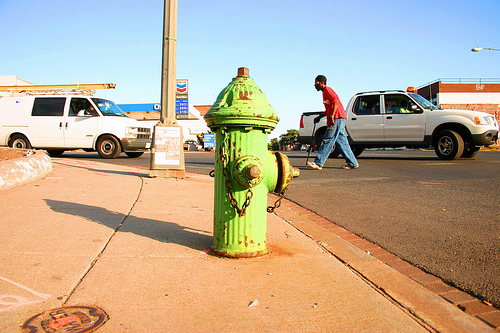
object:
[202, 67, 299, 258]
hydrant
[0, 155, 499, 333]
sidewalk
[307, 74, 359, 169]
person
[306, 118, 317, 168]
cane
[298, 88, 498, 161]
vehicle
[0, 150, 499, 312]
street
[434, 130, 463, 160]
wheel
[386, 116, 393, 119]
handles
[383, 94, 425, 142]
door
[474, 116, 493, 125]
headlight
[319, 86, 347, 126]
shirt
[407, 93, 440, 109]
windshield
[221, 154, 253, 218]
chain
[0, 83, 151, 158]
van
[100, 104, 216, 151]
station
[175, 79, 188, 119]
sign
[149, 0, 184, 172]
pole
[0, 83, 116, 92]
ladder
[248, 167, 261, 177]
rust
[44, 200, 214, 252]
shadow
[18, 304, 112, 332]
cover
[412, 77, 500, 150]
building